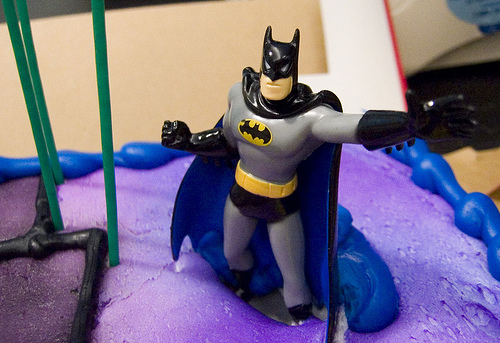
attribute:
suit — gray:
[220, 86, 332, 311]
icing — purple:
[1, 141, 497, 341]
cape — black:
[251, 78, 343, 140]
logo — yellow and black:
[234, 111, 275, 149]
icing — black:
[0, 176, 107, 341]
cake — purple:
[1, 138, 498, 335]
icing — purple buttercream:
[113, 251, 210, 334]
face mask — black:
[252, 22, 301, 95]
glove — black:
[357, 93, 480, 155]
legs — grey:
[216, 194, 313, 325]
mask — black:
[253, 67, 298, 98]